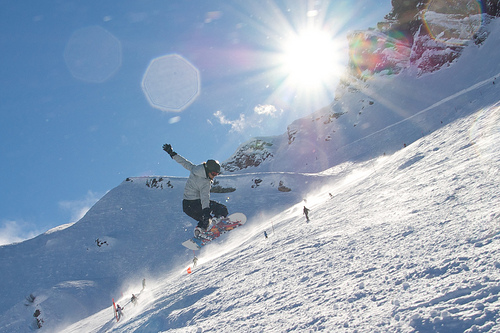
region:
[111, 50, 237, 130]
a circular light reflection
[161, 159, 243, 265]
person is in air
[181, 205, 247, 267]
a colorful snowboard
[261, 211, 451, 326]
the snow is bright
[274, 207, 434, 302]
snow is not fresh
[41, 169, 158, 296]
large snow mountain background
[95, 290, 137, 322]
person with red board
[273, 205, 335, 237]
a person is all black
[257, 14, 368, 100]
sun is shining bright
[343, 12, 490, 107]
rocky mountain in back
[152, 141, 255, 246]
person doing a trick on a snowboard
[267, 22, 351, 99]
sun glaring over the mountain top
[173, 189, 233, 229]
man wearing black pants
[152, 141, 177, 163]
person wearing black glove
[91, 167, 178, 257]
mountain with snow on it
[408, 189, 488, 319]
snow on the ground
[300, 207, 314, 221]
person skiing on the slopes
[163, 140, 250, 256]
person snowboarding down a slope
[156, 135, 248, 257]
person jumping while snowboarding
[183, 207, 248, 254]
snowboard is white with a colorful design on the bottom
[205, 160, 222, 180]
snowboarder wearing a black helmet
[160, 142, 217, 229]
snowboarder wearing black gloves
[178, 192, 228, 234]
snowboarder wearing black pants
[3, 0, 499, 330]
ski slope is bright and white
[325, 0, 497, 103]
rocky peak of mountain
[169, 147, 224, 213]
snowboarder is wearing a white jacket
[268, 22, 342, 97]
the sun is bright and glaring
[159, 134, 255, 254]
a person is on a snowboard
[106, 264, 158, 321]
snow is spraying up around skiers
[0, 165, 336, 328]
snow covered hills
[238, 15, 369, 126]
sun is shining over a hill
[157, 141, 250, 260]
snowboarder wears a helmet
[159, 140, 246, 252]
snowboarder wears black gloves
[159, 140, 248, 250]
snowboarder wears a white jacket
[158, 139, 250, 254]
snowboarder wears black pants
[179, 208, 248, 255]
colorful underside of a snowboard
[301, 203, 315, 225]
a person is skiing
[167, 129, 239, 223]
snow boarder doing tricks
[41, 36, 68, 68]
white snow on the ground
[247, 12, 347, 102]
sun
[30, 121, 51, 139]
white snow on the ground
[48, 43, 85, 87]
white snow on the ground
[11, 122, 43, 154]
white snow on the ground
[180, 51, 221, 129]
white snow on the ground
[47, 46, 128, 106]
white snow on the ground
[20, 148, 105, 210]
white snow on the ground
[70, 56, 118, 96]
white snow on the ground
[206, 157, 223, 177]
Helmet on a snowboarder.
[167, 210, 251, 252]
Snowboard being jumped in the air.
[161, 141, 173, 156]
Glove on a hand.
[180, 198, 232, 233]
Black snow pants on a snowboarder.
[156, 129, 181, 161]
Hand in the air.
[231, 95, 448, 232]
Rock and snow covered hill.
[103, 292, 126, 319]
Person snowboarding on a hill.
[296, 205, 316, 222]
Person riding a snowboard.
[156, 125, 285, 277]
Person jumping a snowboard.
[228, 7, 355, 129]
Sun in the sky over a mountain.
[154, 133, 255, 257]
man in white coat in air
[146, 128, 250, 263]
man in white coat in air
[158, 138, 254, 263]
man in white coat in air